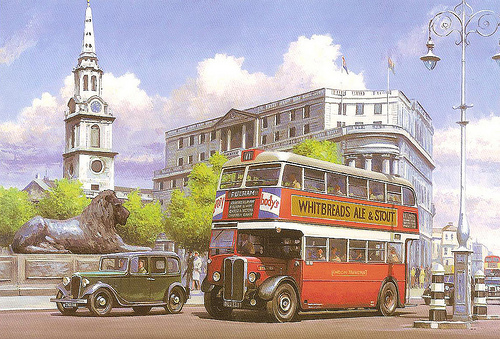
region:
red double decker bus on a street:
[200, 143, 420, 323]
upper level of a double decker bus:
[206, 145, 416, 235]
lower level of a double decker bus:
[196, 220, 422, 317]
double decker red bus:
[201, 149, 421, 322]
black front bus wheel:
[259, 281, 301, 321]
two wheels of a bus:
[263, 273, 398, 321]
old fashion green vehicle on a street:
[50, 248, 188, 318]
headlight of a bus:
[243, 269, 259, 283]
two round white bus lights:
[208, 268, 258, 283]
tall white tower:
[62, 1, 119, 196]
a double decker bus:
[183, 136, 462, 336]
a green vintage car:
[48, 254, 183, 333]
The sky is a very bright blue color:
[358, 18, 368, 38]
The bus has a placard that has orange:
[286, 193, 409, 229]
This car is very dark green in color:
[113, 242, 161, 332]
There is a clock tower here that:
[89, 93, 106, 105]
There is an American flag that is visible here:
[382, 43, 398, 78]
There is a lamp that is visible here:
[416, 43, 448, 86]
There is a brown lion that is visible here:
[40, 188, 137, 273]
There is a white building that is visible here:
[353, 80, 372, 123]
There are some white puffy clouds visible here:
[136, 80, 146, 119]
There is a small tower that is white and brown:
[429, 258, 448, 335]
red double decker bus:
[198, 145, 427, 325]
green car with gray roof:
[49, 240, 200, 319]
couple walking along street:
[183, 245, 209, 295]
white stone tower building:
[59, 3, 124, 205]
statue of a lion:
[6, 185, 157, 260]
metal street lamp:
[413, 4, 498, 319]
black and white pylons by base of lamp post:
[424, 253, 493, 325]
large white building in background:
[150, 77, 446, 172]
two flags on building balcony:
[332, 43, 407, 133]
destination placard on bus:
[222, 185, 267, 225]